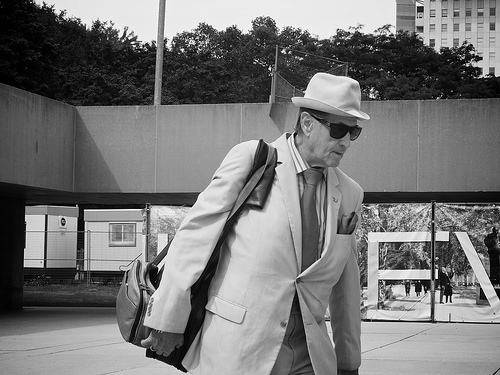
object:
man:
[142, 71, 368, 374]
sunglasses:
[304, 110, 362, 141]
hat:
[291, 71, 370, 122]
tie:
[301, 168, 320, 270]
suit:
[142, 132, 366, 374]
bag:
[113, 258, 163, 345]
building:
[411, 1, 499, 80]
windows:
[453, 23, 459, 32]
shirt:
[286, 132, 326, 268]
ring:
[151, 346, 155, 350]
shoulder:
[229, 137, 271, 172]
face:
[317, 114, 364, 168]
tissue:
[339, 212, 358, 234]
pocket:
[335, 234, 349, 260]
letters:
[368, 230, 450, 310]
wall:
[1, 85, 500, 190]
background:
[1, 1, 499, 98]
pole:
[153, 1, 166, 105]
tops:
[0, 1, 480, 100]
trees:
[1, 1, 48, 84]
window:
[355, 202, 499, 323]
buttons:
[296, 277, 302, 284]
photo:
[0, 1, 499, 375]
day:
[0, 0, 500, 374]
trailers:
[25, 205, 78, 271]